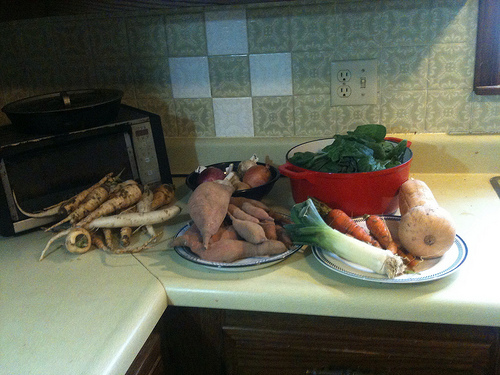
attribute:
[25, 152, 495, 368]
countertop — white 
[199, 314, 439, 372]
cabinets — brown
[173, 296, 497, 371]
cabinets — wood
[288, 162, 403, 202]
pot — red 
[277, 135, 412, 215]
pot — red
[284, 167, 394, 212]
bowl — red